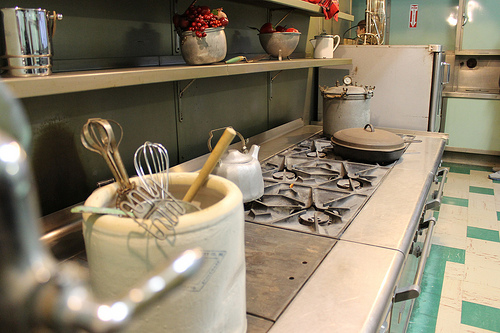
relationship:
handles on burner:
[407, 164, 447, 299] [235, 124, 414, 235]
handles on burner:
[390, 167, 446, 302] [235, 124, 414, 235]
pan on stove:
[330, 124, 404, 164] [271, 107, 441, 235]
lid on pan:
[331, 125, 406, 152] [330, 124, 404, 164]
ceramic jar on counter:
[79, 171, 246, 333] [245, 219, 405, 332]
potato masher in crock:
[121, 132, 191, 244] [81, 160, 249, 324]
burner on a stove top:
[264, 153, 387, 235] [326, 155, 391, 194]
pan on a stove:
[330, 130, 412, 162] [285, 154, 357, 227]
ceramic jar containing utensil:
[73, 168, 256, 331] [74, 112, 147, 213]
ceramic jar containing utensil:
[73, 168, 256, 331] [110, 170, 191, 247]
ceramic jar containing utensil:
[73, 168, 256, 331] [180, 119, 237, 204]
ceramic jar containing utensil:
[73, 168, 256, 331] [126, 136, 173, 204]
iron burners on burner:
[280, 154, 355, 234] [235, 124, 414, 235]